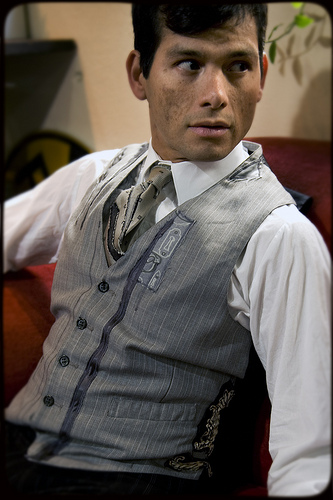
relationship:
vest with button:
[4, 143, 297, 482] [101, 281, 109, 293]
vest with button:
[4, 143, 297, 482] [75, 318, 85, 332]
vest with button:
[4, 143, 297, 482] [57, 354, 68, 372]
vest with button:
[4, 143, 297, 482] [39, 392, 53, 410]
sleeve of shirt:
[244, 210, 331, 495] [0, 137, 332, 499]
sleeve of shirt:
[1, 145, 136, 274] [0, 137, 332, 499]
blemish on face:
[165, 88, 173, 96] [151, 16, 261, 159]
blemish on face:
[171, 94, 178, 101] [151, 16, 261, 159]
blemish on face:
[159, 108, 167, 115] [151, 16, 261, 159]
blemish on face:
[170, 110, 180, 120] [151, 16, 261, 159]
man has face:
[0, 0, 332, 483] [151, 16, 261, 159]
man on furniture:
[0, 0, 332, 483] [3, 137, 327, 491]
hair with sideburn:
[130, 5, 268, 56] [143, 53, 161, 78]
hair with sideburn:
[130, 5, 268, 56] [256, 49, 263, 77]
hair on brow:
[130, 5, 268, 56] [163, 24, 257, 58]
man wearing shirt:
[0, 0, 332, 483] [0, 137, 332, 499]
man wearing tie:
[0, 0, 332, 483] [107, 165, 170, 259]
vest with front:
[4, 143, 297, 482] [13, 126, 239, 450]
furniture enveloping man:
[3, 137, 327, 491] [0, 0, 332, 483]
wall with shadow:
[1, 4, 332, 157] [291, 68, 330, 133]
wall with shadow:
[1, 4, 332, 157] [43, 48, 93, 155]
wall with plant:
[1, 4, 332, 157] [265, 2, 330, 87]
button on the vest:
[97, 281, 109, 294] [27, 167, 304, 354]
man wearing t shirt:
[0, 0, 332, 483] [3, 138, 330, 496]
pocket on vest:
[103, 398, 199, 446] [4, 143, 297, 482]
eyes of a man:
[158, 45, 257, 86] [0, 0, 332, 483]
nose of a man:
[200, 66, 229, 109] [0, 0, 332, 483]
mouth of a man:
[185, 118, 229, 136] [0, 0, 332, 483]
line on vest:
[38, 215, 175, 461] [4, 143, 297, 482]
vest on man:
[4, 143, 297, 482] [0, 0, 332, 483]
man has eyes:
[0, 0, 332, 483] [227, 59, 252, 75]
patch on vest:
[136, 211, 195, 291] [80, 15, 117, 56]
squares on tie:
[134, 212, 141, 221] [101, 160, 178, 270]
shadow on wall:
[264, 11, 332, 136] [37, 4, 332, 152]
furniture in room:
[2, 38, 89, 202] [8, 9, 332, 363]